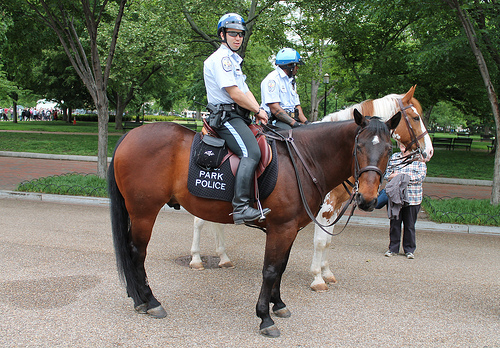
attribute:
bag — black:
[198, 113, 236, 166]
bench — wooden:
[433, 128, 475, 154]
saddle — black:
[190, 116, 277, 203]